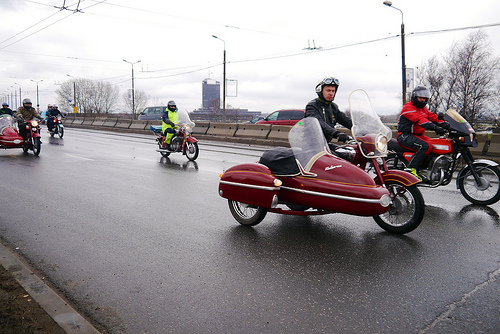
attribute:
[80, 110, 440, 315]
pavement — wet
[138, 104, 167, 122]
car — blue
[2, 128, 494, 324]
road — wet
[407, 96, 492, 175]
bike — red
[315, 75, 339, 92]
helmet — white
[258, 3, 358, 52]
sky — blue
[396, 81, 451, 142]
rider — red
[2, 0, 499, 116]
clouds — white, gray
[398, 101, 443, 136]
jacket — red, black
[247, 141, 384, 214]
bike — red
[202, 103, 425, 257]
motorcycle — maroon, red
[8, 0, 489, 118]
sky — blue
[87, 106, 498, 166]
side — other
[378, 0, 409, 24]
light — street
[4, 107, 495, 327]
street — full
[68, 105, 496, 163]
side — other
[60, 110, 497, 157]
divider — concrete, center, barrier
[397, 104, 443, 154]
outfit — red